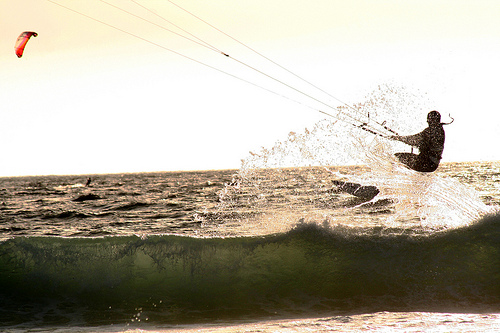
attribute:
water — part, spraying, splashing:
[18, 180, 94, 204]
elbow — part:
[403, 138, 424, 144]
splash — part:
[364, 174, 437, 208]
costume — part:
[394, 130, 465, 172]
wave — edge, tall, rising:
[315, 197, 413, 253]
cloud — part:
[287, 0, 346, 42]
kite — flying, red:
[20, 28, 49, 61]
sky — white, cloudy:
[105, 55, 139, 69]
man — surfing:
[403, 89, 465, 205]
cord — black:
[190, 35, 299, 104]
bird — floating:
[49, 170, 93, 189]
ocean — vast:
[52, 164, 262, 324]